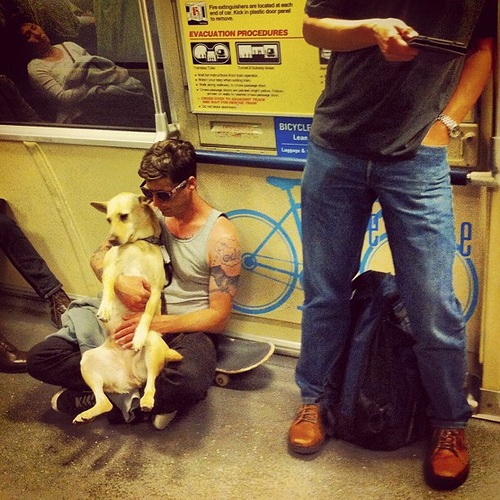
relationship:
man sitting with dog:
[28, 132, 257, 413] [72, 186, 188, 430]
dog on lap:
[72, 186, 188, 430] [58, 310, 180, 379]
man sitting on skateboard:
[28, 132, 257, 413] [214, 331, 274, 389]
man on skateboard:
[28, 132, 257, 413] [214, 331, 274, 389]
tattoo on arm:
[207, 238, 246, 296] [161, 217, 243, 335]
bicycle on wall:
[210, 171, 487, 346] [5, 2, 497, 421]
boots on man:
[283, 407, 478, 492] [265, 5, 495, 492]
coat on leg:
[47, 293, 109, 355] [23, 293, 107, 395]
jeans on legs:
[24, 325, 221, 409] [15, 330, 225, 412]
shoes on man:
[46, 391, 180, 432] [28, 132, 257, 413]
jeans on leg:
[24, 325, 221, 409] [23, 293, 107, 395]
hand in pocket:
[421, 119, 464, 143] [410, 144, 448, 182]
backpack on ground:
[325, 269, 430, 453] [5, 289, 500, 492]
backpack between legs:
[325, 269, 430, 453] [301, 143, 458, 418]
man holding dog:
[28, 132, 257, 413] [72, 186, 188, 430]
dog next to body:
[72, 186, 188, 430] [17, 198, 242, 428]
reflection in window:
[9, 17, 135, 116] [5, 0, 175, 132]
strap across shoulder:
[62, 43, 78, 68] [50, 39, 80, 59]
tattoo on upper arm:
[207, 238, 246, 304] [211, 222, 243, 311]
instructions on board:
[179, 4, 304, 106] [177, 0, 335, 121]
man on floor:
[28, 132, 257, 413] [4, 295, 499, 498]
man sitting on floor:
[28, 132, 257, 413] [4, 295, 499, 498]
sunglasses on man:
[136, 177, 188, 200] [28, 132, 257, 413]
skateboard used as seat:
[214, 331, 274, 389] [211, 333, 273, 378]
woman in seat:
[15, 13, 152, 116] [5, 6, 64, 120]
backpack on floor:
[325, 269, 430, 453] [4, 295, 499, 498]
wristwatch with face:
[443, 112, 466, 136] [450, 123, 465, 139]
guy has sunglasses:
[21, 134, 246, 432] [136, 177, 188, 203]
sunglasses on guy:
[136, 177, 188, 203] [21, 134, 246, 432]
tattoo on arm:
[207, 238, 246, 304] [161, 217, 243, 335]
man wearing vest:
[28, 132, 257, 413] [135, 210, 222, 323]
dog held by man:
[72, 186, 188, 430] [28, 132, 257, 413]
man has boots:
[265, 5, 495, 492] [285, 396, 329, 458]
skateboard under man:
[214, 331, 274, 389] [28, 132, 257, 413]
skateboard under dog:
[214, 331, 274, 389] [72, 186, 188, 430]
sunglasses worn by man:
[136, 177, 188, 200] [28, 132, 257, 413]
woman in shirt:
[15, 13, 152, 116] [27, 36, 96, 110]